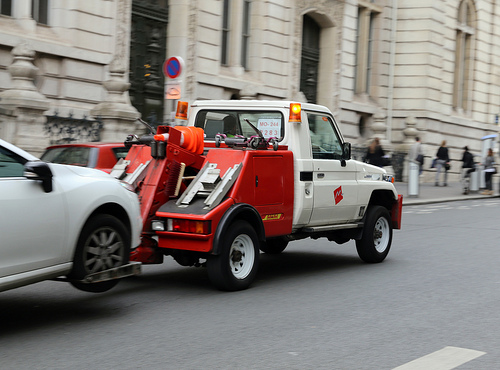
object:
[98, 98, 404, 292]
car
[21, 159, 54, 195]
mirror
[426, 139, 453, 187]
people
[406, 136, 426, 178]
people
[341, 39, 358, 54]
stone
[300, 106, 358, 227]
door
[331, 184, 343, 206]
logo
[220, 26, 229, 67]
windows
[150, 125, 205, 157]
cones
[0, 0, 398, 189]
building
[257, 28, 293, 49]
stone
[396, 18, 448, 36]
stone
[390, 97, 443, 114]
stone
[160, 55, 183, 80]
sign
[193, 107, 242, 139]
window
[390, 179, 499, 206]
pavement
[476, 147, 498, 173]
people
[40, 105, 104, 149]
metal gate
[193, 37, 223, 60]
stone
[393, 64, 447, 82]
stone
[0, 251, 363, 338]
shadow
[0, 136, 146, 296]
car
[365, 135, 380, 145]
hair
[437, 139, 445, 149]
hair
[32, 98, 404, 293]
tow truck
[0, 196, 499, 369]
street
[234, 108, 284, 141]
window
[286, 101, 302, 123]
light